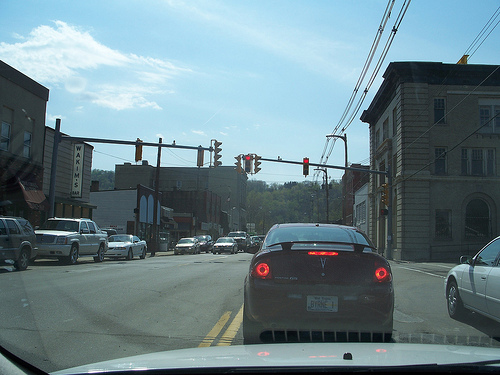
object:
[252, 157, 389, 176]
pole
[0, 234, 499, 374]
street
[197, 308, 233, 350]
lines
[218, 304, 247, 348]
lines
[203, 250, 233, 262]
lines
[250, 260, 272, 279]
tail light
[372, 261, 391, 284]
tail light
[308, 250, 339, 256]
tail light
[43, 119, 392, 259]
lights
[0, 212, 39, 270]
truck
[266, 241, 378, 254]
spoiler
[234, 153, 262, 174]
lights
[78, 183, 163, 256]
building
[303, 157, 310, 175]
light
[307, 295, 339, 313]
license plate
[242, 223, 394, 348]
black car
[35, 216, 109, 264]
cars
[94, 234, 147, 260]
cars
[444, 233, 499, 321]
white car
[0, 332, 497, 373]
white car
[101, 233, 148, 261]
white car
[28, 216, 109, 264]
truck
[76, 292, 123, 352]
asphalt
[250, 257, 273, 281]
light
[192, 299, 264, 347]
lines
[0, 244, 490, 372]
road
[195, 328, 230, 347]
lines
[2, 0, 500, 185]
sky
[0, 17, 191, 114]
thin clouds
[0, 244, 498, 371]
pavement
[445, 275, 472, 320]
tire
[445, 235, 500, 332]
car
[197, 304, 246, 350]
line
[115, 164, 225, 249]
bars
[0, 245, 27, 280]
curb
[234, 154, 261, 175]
signals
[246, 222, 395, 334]
car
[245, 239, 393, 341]
back